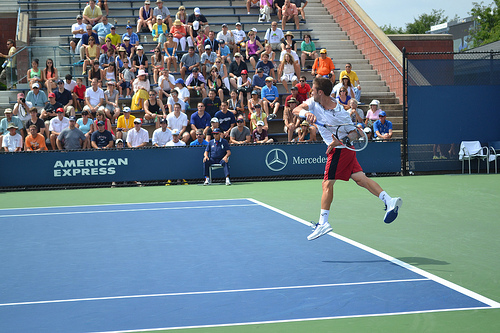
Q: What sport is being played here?
A: Tennis.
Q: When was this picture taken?
A: Daytime.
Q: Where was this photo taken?
A: A tennis court.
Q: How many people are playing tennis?
A: One.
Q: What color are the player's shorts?
A: Red.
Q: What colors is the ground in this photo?
A: Green and blue.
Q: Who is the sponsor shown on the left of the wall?
A: American Express.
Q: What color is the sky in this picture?
A: Blue.